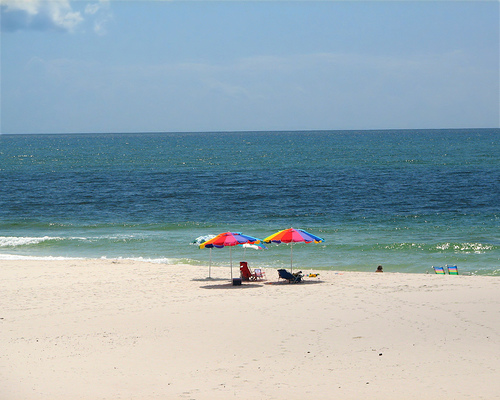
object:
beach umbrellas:
[198, 229, 264, 285]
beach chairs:
[432, 266, 447, 276]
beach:
[0, 253, 497, 398]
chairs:
[239, 261, 263, 281]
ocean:
[0, 127, 500, 276]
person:
[374, 265, 384, 273]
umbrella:
[189, 234, 221, 279]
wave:
[0, 236, 500, 254]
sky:
[0, 0, 496, 137]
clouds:
[0, 0, 117, 38]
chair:
[254, 268, 268, 280]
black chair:
[276, 268, 305, 284]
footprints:
[187, 283, 492, 399]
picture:
[0, 0, 500, 400]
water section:
[0, 169, 500, 226]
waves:
[0, 218, 227, 232]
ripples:
[380, 241, 500, 256]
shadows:
[199, 283, 264, 289]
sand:
[0, 257, 499, 400]